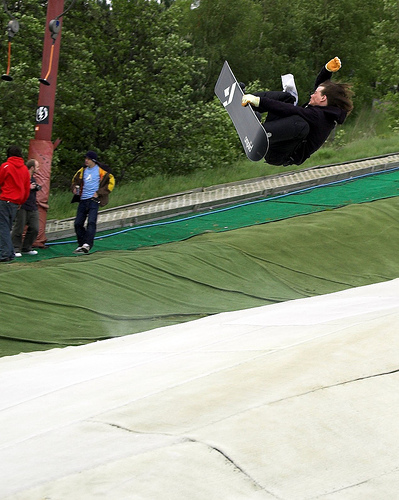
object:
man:
[244, 46, 354, 173]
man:
[66, 146, 115, 257]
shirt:
[78, 168, 102, 203]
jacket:
[66, 164, 119, 208]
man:
[3, 147, 34, 267]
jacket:
[2, 156, 33, 207]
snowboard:
[209, 62, 274, 167]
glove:
[240, 91, 260, 111]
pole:
[26, 6, 69, 248]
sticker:
[31, 103, 52, 126]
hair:
[321, 79, 351, 113]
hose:
[33, 175, 398, 245]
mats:
[16, 163, 398, 246]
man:
[25, 156, 45, 265]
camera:
[36, 181, 47, 195]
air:
[2, 4, 398, 348]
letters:
[243, 137, 258, 158]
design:
[217, 81, 242, 111]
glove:
[321, 55, 344, 76]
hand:
[323, 53, 346, 78]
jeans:
[71, 198, 101, 253]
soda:
[34, 180, 45, 198]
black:
[252, 72, 337, 169]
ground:
[3, 287, 392, 499]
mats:
[2, 195, 398, 345]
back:
[1, 159, 29, 257]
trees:
[3, 3, 398, 185]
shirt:
[262, 92, 342, 160]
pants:
[259, 113, 308, 167]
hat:
[84, 151, 96, 163]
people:
[5, 146, 132, 266]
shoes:
[15, 249, 42, 259]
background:
[3, 6, 398, 330]